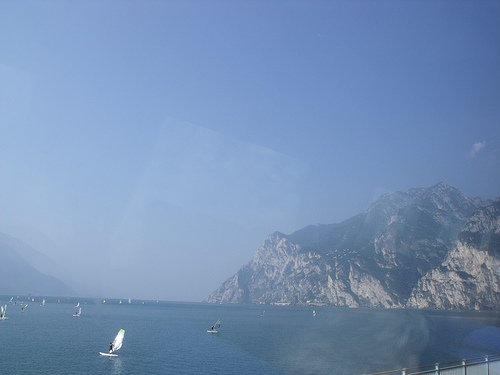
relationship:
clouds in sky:
[468, 134, 489, 157] [2, 3, 498, 301]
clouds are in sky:
[468, 134, 489, 157] [391, 105, 450, 157]